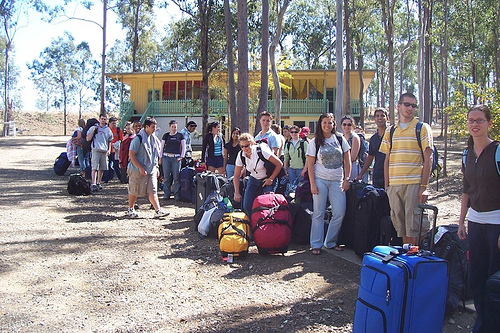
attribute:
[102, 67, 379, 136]
cabin — yellow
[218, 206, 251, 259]
bag — small, yellow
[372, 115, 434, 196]
shirt — striped, white, yellwo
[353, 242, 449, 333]
luggage — large, blue, black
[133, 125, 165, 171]
sweatshirt — gray, grey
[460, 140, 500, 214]
vest — black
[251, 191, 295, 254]
duffel — strapped, large, red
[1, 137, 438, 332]
road — gravel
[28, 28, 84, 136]
tree — thin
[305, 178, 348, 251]
jeans — denim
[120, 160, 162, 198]
shorts — tan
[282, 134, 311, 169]
top — green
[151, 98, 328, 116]
railing — green